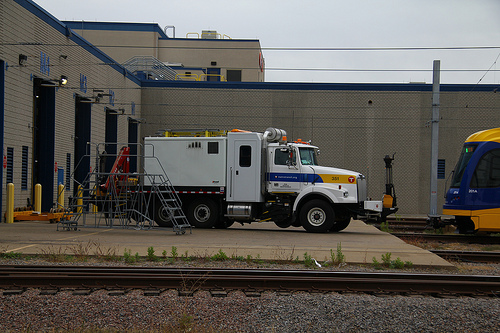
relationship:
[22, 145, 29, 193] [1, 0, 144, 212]
vent on wall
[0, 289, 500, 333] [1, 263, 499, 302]
gravel laid next to track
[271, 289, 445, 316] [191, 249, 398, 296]
gravel on side of tracks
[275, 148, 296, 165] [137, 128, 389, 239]
window on truck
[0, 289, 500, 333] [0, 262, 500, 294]
gravel next to train tracks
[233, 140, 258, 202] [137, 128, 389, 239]
door on truck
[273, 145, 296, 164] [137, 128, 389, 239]
window in truck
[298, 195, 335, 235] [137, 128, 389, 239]
tire on truck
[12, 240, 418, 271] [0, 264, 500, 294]
weeds next to rails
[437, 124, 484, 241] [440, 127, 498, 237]
front of a train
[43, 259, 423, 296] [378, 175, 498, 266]
rails of a track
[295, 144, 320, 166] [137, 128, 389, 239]
windshield of a truck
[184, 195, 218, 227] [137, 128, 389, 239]
wheel of a truck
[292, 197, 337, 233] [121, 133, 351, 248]
wheel of a truck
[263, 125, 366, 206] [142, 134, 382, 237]
cab of a truck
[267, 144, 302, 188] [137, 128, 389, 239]
passenger door of a truck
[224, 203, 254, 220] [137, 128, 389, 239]
gas tank of a truck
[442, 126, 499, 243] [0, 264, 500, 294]
train on rails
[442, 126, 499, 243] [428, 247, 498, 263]
train on track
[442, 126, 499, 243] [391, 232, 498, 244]
train on track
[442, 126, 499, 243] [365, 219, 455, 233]
train on track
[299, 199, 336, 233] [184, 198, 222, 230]
wheel on wheel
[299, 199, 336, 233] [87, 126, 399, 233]
wheel on truck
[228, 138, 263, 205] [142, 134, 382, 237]
door on truck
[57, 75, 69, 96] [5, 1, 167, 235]
light connected to building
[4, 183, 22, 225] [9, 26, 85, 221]
pole by building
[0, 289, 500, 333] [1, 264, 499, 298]
gravel alongside train tracks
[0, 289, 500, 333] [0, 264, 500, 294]
gravel support weight on rails